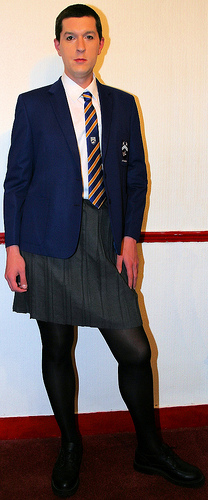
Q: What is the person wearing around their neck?
A: A neck tie.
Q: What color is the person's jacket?
A: Blue.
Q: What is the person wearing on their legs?
A: Stockings.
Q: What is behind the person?
A: The wall.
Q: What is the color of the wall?
A: White.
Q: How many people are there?
A: One.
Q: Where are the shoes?
A: On the person's feet.